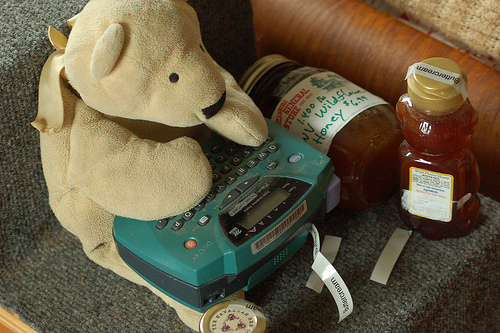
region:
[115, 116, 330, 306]
an old green label maker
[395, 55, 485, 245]
a bear honey jar with lid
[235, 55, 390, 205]
a jar of wild honey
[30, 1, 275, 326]
a tan teddy bear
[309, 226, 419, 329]
printed labels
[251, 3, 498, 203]
a wooden chair arm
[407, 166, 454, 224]
label on a honey jar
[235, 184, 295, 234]
a digital display on the label maker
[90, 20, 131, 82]
a tan teddy bear ear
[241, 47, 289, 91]
a metal lid on the honey jar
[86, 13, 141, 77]
ear of a teddy bear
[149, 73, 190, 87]
eye of a teddy bear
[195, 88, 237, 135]
nose of a teddy bear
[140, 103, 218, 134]
mouth of a teddy bear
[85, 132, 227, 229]
arm of a teddy bear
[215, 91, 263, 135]
arm of a teddy bear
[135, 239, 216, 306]
leg of a teddy bear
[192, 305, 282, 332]
feet of a teddy bear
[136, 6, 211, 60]
top of a teddy bear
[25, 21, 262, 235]
body of a teddy bear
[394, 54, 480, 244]
The container of honey is full.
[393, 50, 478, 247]
The honey is brown in color.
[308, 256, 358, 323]
The tag has black writing.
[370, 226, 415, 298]
The tag is white.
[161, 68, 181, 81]
The teddy bears right eye is brown.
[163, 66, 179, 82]
The teddy bears right eye is round.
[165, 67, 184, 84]
The teddy bears right eye is small.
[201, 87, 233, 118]
The teddy bears nose is brown.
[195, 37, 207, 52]
The teddy bears left eye is brown.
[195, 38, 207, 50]
The teddy bears left eye is round.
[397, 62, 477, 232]
bottle of honey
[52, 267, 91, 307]
the carpet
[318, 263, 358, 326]
a sticker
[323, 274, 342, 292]
writing on the sticker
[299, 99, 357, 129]
writing on the bottle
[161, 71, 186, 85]
an eye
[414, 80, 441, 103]
the top of the honey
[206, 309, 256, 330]
a bottle top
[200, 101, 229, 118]
nose of the teddy bear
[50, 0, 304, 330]
a teddy bear holding a labeler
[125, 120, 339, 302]
the labeler sitting on the bears lap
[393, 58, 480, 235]
a little honey jar sitting on the chair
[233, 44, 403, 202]
a jar of honey sitting on the table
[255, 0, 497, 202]
the wooden side of the chair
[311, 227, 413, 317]
pieces of paper on the chair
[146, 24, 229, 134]
the happy face of the bear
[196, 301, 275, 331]
the tag on the bear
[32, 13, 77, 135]
the bow on the back of the bears neck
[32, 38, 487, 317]
a little kids picnic with her bear and honey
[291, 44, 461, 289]
someone loves all different types of honey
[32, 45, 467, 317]
the stuffed bear is playing a song about his love for honey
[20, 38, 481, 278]
stuffed bear is printing out labels to put on honey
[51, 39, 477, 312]
kids bear is labeling different types of honey to put in cupboard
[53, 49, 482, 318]
mom is putting collectables together with old teddy and honey jars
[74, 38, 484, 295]
label maker collected dust over the years but still makes tags for honey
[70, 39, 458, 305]
teddy bear sits on stairs making labels for honey jars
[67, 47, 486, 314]
all of the important collectables on the stairs to the closet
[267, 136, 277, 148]
a key on a keyboard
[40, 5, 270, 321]
a toy stuffed animal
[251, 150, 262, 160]
a key on a keyboard